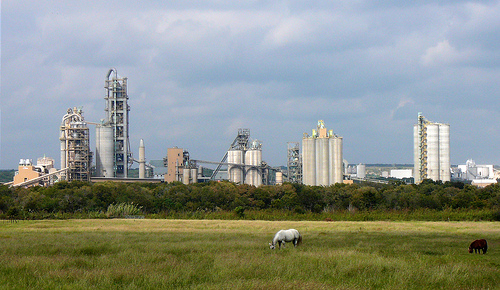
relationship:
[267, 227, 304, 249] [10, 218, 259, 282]
horse grazing in field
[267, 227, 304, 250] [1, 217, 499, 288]
horse grazing in grass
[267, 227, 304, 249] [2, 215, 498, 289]
horse in field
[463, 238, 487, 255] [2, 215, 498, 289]
brown horse in field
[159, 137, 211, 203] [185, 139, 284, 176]
buildings in mill with conveyor belt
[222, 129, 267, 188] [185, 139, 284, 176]
building in mill with conveyor belt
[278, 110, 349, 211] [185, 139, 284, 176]
buildings in mill with conveyor belt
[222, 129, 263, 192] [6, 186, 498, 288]
building behind field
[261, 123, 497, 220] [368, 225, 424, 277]
building behind field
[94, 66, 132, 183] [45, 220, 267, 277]
building behind field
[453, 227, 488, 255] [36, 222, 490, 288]
brown horse on field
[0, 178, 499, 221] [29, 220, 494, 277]
trees behind field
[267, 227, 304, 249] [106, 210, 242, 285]
horse on field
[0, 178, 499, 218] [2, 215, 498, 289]
trees on field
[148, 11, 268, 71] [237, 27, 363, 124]
clouds in sky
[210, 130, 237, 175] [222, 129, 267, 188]
conveyer belt on building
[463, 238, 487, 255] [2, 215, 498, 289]
brown horse on field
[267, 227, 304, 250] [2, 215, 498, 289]
horse on field